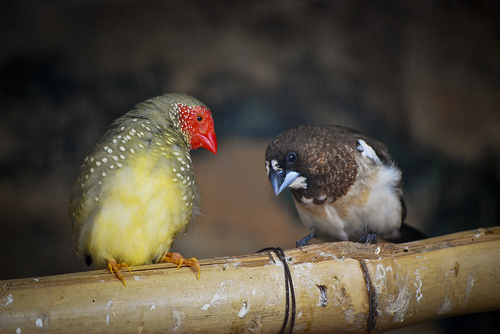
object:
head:
[174, 94, 220, 156]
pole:
[0, 226, 498, 331]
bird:
[73, 91, 226, 271]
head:
[263, 131, 311, 194]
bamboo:
[0, 221, 499, 333]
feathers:
[350, 170, 402, 236]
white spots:
[374, 293, 414, 323]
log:
[5, 228, 500, 334]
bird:
[262, 113, 432, 263]